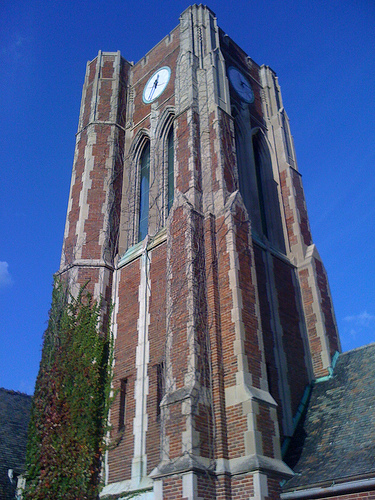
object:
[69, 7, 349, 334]
building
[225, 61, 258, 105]
clock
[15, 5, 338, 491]
tower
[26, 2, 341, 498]
building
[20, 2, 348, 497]
brick building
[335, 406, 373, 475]
shingles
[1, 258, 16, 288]
cloud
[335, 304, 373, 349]
cloud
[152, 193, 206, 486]
vine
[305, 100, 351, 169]
sky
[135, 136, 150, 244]
window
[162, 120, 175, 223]
window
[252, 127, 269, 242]
window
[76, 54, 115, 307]
brick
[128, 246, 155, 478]
stone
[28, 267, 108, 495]
vines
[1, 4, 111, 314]
sky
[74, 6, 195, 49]
sky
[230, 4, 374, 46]
sky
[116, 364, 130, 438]
window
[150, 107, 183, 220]
window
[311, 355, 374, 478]
roof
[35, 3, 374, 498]
building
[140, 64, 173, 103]
clock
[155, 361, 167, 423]
window